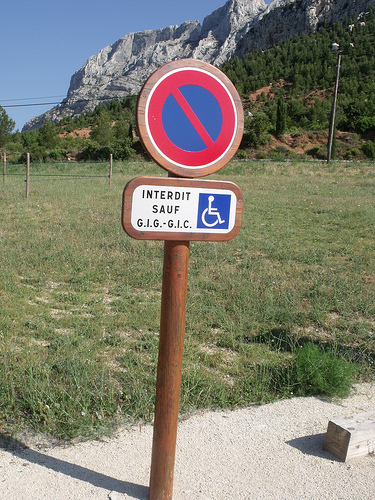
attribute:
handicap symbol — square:
[197, 190, 231, 230]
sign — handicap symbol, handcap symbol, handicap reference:
[122, 176, 245, 242]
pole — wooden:
[150, 169, 192, 498]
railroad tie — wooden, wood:
[324, 413, 375, 462]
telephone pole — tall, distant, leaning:
[327, 52, 343, 159]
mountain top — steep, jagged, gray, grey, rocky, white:
[67, 4, 375, 102]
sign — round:
[137, 57, 247, 176]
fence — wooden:
[2, 151, 115, 192]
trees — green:
[22, 24, 374, 160]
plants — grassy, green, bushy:
[281, 343, 350, 395]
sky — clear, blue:
[0, 1, 277, 132]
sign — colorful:
[120, 58, 245, 497]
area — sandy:
[248, 76, 285, 104]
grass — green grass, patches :
[2, 162, 372, 446]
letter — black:
[136, 218, 143, 227]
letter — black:
[145, 216, 152, 230]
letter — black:
[146, 188, 154, 201]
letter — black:
[184, 218, 191, 234]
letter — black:
[151, 204, 160, 216]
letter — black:
[160, 204, 165, 214]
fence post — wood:
[25, 150, 35, 202]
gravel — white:
[4, 380, 375, 498]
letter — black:
[173, 206, 181, 216]